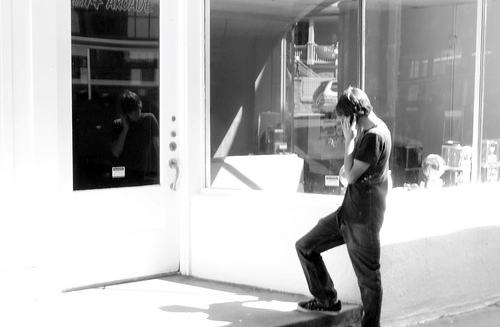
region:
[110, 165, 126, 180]
small sign on the shop door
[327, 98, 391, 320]
man talking on a cell phone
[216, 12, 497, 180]
reflective glass shop window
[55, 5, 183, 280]
white door of the store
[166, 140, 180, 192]
metal door handle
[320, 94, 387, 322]
man climbing a step into the shore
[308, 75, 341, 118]
reflection of a car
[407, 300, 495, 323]
sidewalk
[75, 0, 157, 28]
arcade shop sign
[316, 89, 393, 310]
man wearing jeans and a t-shirt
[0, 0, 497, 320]
a guy on the cell phone in front of a business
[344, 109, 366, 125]
a man holding a cell phone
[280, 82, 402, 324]
a guy wearing black tennis shoes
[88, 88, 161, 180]
a guys relfection in the window of the door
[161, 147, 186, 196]
a door handle to open door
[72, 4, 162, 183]
window in a door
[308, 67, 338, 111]
a car reflecting in the window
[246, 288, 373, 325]
a guy puts foot up on a step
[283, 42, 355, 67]
a balcony can be seen through window reflection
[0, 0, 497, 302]
a white building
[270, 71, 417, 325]
a man standing on the street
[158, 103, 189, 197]
a silver door handle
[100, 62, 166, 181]
the reflection of a man in the window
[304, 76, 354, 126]
the reflection of a car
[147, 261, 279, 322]
the man's shadow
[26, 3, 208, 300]
a white door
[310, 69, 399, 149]
the head of a man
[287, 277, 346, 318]
a man's shoes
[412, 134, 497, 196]
store items in the window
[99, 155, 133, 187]
a sticker on the door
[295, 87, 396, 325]
man holds a cellphone to his ear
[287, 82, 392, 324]
man is stepping up a step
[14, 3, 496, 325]
man on a step outside a store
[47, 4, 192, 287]
store entrance door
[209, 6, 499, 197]
store display window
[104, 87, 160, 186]
reflection of a man in a door window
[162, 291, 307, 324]
shadow of a man on a step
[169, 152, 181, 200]
door handle is low down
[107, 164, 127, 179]
sticker on the window of a door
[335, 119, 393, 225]
t-shirt on a man entering a store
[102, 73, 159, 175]
Reflection of the person on the phone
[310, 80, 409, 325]
Person on a cell phone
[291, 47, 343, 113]
Reflextion of a car across the street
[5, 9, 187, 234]
Door to a shop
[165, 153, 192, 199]
The door handle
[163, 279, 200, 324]
Shadow of the persons head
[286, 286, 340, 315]
The persons right tennis shoe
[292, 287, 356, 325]
Front step tp hte shop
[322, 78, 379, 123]
The persons head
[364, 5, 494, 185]
The shop front window.